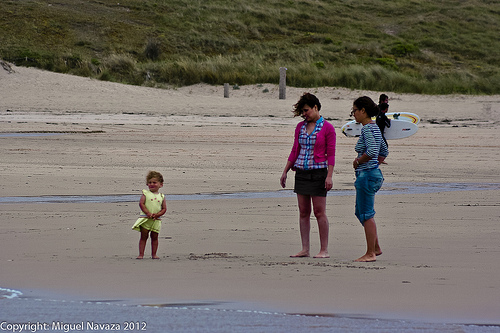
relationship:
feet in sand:
[287, 251, 329, 261] [0, 118, 497, 329]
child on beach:
[132, 170, 168, 259] [5, 4, 498, 326]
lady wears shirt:
[280, 92, 337, 258] [285, 118, 335, 165]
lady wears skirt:
[280, 92, 337, 258] [288, 168, 329, 196]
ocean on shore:
[1, 287, 500, 333] [0, 282, 498, 332]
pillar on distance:
[272, 62, 291, 101] [9, 46, 494, 99]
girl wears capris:
[349, 96, 389, 262] [354, 168, 384, 227]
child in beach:
[132, 170, 168, 259] [20, 262, 441, 331]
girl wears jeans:
[347, 97, 386, 259] [357, 172, 382, 218]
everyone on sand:
[128, 87, 385, 276] [31, 132, 437, 301]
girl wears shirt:
[349, 96, 389, 262] [352, 121, 389, 171]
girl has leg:
[349, 96, 389, 262] [350, 177, 388, 268]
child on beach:
[132, 170, 168, 259] [0, 59, 499, 331]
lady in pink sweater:
[280, 92, 337, 258] [288, 114, 335, 168]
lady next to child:
[280, 92, 337, 258] [130, 169, 168, 259]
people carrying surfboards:
[375, 91, 391, 137] [328, 88, 453, 154]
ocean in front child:
[1, 287, 498, 332] [132, 170, 168, 259]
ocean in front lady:
[1, 287, 498, 332] [280, 92, 337, 258]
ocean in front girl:
[1, 287, 498, 332] [349, 96, 389, 262]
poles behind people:
[224, 67, 286, 99] [127, 91, 389, 268]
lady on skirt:
[280, 92, 337, 258] [292, 170, 328, 197]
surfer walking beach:
[374, 93, 391, 164] [0, 59, 499, 331]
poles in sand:
[217, 62, 297, 99] [2, 63, 492, 330]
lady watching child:
[280, 92, 337, 258] [132, 170, 168, 259]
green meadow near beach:
[413, 0, 498, 91] [0, 59, 499, 331]